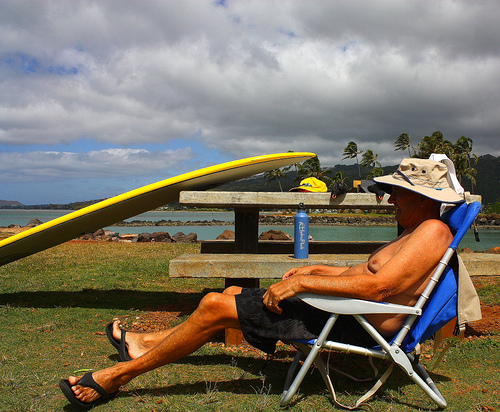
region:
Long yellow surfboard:
[0, 143, 320, 281]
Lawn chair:
[265, 191, 486, 408]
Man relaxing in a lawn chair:
[58, 149, 467, 407]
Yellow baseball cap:
[283, 168, 328, 198]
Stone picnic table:
[159, 177, 482, 353]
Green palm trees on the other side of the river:
[335, 132, 385, 177]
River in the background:
[1, 195, 497, 255]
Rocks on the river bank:
[70, 221, 290, 244]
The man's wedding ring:
[265, 295, 275, 302]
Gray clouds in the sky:
[0, 0, 498, 151]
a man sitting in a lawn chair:
[64, 144, 492, 404]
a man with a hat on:
[367, 138, 480, 236]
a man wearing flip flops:
[38, 308, 150, 410]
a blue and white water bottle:
[286, 198, 317, 261]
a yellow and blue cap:
[286, 170, 329, 192]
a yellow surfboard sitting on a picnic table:
[3, 147, 319, 353]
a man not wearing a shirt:
[261, 138, 486, 353]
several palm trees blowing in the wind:
[263, 127, 478, 197]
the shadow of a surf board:
[3, 275, 201, 317]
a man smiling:
[373, 175, 426, 225]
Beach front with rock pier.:
[4, 193, 496, 260]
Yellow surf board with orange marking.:
[4, 148, 328, 267]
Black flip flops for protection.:
[54, 323, 159, 400]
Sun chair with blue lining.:
[288, 199, 475, 407]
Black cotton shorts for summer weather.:
[225, 278, 398, 365]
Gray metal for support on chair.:
[279, 192, 484, 410]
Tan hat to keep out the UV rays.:
[375, 156, 469, 210]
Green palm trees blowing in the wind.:
[248, 129, 487, 194]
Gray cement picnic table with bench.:
[156, 183, 497, 359]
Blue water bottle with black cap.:
[291, 199, 316, 257]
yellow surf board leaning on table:
[1, 150, 319, 270]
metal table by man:
[177, 188, 497, 282]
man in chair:
[63, 158, 471, 403]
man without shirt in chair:
[64, 162, 478, 403]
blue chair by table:
[278, 195, 480, 409]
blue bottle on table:
[290, 208, 312, 258]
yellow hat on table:
[295, 176, 325, 188]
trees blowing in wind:
[391, 135, 479, 175]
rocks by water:
[138, 228, 195, 240]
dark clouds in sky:
[228, 80, 483, 145]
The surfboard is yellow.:
[0, 148, 317, 273]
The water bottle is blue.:
[293, 200, 310, 261]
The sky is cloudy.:
[2, 2, 497, 152]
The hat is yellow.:
[288, 173, 332, 193]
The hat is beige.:
[372, 154, 467, 205]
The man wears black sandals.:
[58, 313, 151, 408]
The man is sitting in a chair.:
[58, 154, 484, 409]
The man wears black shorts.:
[238, 289, 378, 348]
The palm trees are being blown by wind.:
[341, 129, 475, 170]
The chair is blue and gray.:
[398, 197, 483, 353]